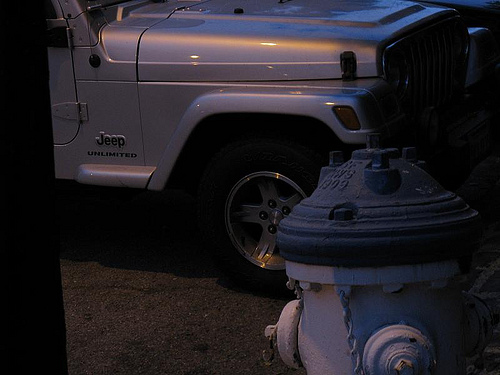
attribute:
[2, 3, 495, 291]
jeep — grey, parked, metallic, shiny, white, beautiful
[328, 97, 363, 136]
light — red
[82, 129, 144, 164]
name — black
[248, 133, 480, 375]
hydran — grey, capped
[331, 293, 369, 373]
chain — white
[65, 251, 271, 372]
concrete — dirty, gray, clear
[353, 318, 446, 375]
hose — white